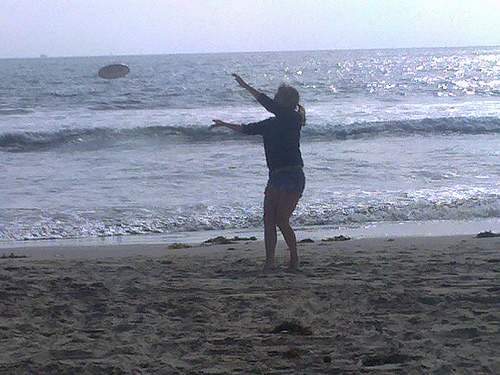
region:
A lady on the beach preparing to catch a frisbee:
[66, 22, 361, 302]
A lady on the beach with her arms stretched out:
[164, 29, 351, 310]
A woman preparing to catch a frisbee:
[62, 38, 367, 290]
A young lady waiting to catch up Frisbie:
[55, 32, 370, 289]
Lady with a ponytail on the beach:
[180, 37, 347, 316]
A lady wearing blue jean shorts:
[186, 66, 356, 296]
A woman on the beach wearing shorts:
[194, 67, 335, 285]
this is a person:
[192, 35, 339, 290]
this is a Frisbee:
[92, 53, 139, 88]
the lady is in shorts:
[254, 163, 317, 190]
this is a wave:
[326, 165, 437, 237]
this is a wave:
[77, 96, 159, 151]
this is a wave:
[345, 100, 457, 154]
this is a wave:
[135, 100, 227, 166]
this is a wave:
[3, 105, 108, 176]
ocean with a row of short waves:
[4, 47, 494, 259]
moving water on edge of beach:
[9, 192, 497, 261]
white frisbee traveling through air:
[36, 30, 189, 145]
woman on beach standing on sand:
[205, 67, 307, 300]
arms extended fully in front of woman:
[206, 65, 310, 149]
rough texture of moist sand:
[7, 248, 489, 363]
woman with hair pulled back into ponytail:
[267, 80, 309, 131]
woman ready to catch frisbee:
[80, 56, 310, 280]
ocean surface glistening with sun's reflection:
[274, 45, 494, 113]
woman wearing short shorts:
[210, 70, 310, 275]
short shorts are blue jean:
[262, 164, 306, 199]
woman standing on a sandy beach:
[201, 64, 311, 280]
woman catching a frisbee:
[95, 59, 310, 271]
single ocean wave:
[0, 102, 498, 154]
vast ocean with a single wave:
[0, 43, 498, 233]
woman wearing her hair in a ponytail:
[207, 70, 308, 272]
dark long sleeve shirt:
[240, 92, 302, 170]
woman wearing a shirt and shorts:
[208, 72, 308, 275]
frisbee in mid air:
[95, 61, 130, 83]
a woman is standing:
[209, 69, 307, 273]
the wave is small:
[0, 116, 497, 151]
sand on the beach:
[2, 219, 496, 374]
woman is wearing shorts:
[264, 169, 305, 196]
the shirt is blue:
[242, 94, 304, 164]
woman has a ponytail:
[297, 101, 306, 123]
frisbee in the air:
[98, 63, 130, 79]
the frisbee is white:
[96, 62, 129, 79]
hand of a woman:
[208, 116, 223, 128]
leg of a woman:
[277, 176, 304, 266]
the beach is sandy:
[75, 264, 339, 369]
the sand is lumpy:
[108, 284, 415, 345]